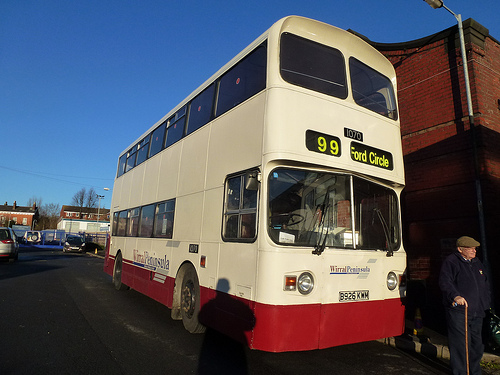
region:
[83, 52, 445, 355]
A two decker bus on the street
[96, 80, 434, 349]
The bus is red and white in color.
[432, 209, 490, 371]
A man with a cane walking.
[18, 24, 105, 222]
The sky is a gorgeous blue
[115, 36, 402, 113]
A huge row of windows.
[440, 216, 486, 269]
An elderly man wearing a hat.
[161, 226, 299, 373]
A person's shadow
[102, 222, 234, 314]
Wirral Peninsula Bus Company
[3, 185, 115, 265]
Two story houses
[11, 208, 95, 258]
Car parked in the street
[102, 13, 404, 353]
double decker bus at the bus stop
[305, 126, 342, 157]
bus route identification number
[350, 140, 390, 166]
bus stop street name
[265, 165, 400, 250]
the buses front windshield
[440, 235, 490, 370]
a man with a cane walking in front of the bus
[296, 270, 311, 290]
the buses headlights are off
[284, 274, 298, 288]
the buses blinker is amber in color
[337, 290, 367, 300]
the buses license plate is displayed in the front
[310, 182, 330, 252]
the buses windshield wipers are off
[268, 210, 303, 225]
bus steering wheel is on the right driver side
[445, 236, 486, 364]
this is a man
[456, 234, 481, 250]
this is a hat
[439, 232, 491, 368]
the man is old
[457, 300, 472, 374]
this is a walking stick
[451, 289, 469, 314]
the man is holding the walking stick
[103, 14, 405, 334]
this is a double decker bus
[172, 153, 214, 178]
the bus is white in color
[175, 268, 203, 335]
this is a wheel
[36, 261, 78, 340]
this is the road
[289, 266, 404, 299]
these are bus headlights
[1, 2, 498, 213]
the bright blue sky above it all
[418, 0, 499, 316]
a metal pole with a light on the top of it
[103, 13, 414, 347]
a red and white double decker bus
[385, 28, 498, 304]
a building with a brick exterior by the bus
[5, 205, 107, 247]
some buildings at the end of the road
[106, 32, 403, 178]
the windows on the top of the bus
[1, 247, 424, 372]
the street for the cars to drive on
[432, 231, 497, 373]
an older man walking down the street with a cane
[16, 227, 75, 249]
cars parked on the end of the road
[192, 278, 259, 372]
a shadow on the bus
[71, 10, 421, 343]
large white and red double Decker bus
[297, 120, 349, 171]
large bus with the number 99 on it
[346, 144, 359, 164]
large bus with the letter F on it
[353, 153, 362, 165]
large bus with the letter o on it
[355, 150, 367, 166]
large bus with the letter r on it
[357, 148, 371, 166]
large bus with the letter d on it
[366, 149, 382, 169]
large bus with the letter C on it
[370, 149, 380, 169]
large bus with the letter i on it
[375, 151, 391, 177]
large bus with the letter l on it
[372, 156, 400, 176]
large bus with the letter e on it